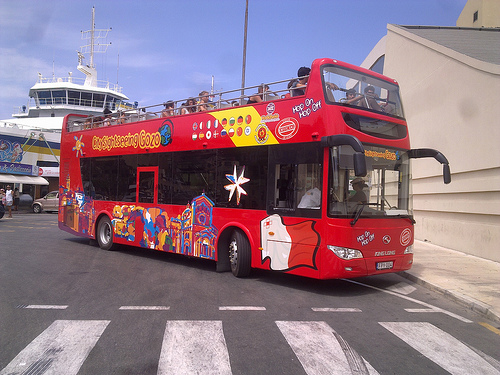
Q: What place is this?
A: It is a road.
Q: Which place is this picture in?
A: It is at the road.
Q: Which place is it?
A: It is a road.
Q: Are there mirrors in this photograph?
A: Yes, there is a mirror.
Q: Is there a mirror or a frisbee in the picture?
A: Yes, there is a mirror.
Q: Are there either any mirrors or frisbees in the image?
A: Yes, there is a mirror.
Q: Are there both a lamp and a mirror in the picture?
A: No, there is a mirror but no lamps.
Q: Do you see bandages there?
A: No, there are no bandages.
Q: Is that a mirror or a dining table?
A: That is a mirror.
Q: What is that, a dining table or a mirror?
A: That is a mirror.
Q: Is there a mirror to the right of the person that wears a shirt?
A: Yes, there is a mirror to the right of the person.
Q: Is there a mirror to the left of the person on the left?
A: No, the mirror is to the right of the person.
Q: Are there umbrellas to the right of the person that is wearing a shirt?
A: No, there is a mirror to the right of the person.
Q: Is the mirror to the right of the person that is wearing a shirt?
A: Yes, the mirror is to the right of the person.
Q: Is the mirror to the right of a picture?
A: No, the mirror is to the right of the person.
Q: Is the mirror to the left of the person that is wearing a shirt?
A: No, the mirror is to the right of the person.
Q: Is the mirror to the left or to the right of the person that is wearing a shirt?
A: The mirror is to the right of the person.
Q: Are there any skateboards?
A: No, there are no skateboards.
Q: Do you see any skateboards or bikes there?
A: No, there are no skateboards or bikes.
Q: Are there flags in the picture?
A: Yes, there is a flag.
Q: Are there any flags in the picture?
A: Yes, there is a flag.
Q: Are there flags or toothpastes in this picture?
A: Yes, there is a flag.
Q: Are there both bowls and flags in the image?
A: No, there is a flag but no bowls.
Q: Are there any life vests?
A: No, there are no life vests.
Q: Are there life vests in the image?
A: No, there are no life vests.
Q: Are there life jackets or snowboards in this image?
A: No, there are no life jackets or snowboards.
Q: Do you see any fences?
A: No, there are no fences.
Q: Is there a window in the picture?
A: Yes, there is a window.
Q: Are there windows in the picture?
A: Yes, there is a window.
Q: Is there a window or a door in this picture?
A: Yes, there is a window.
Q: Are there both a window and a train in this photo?
A: No, there is a window but no trains.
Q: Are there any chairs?
A: No, there are no chairs.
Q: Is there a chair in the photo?
A: No, there are no chairs.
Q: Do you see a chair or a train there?
A: No, there are no chairs or trains.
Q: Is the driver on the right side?
A: Yes, the driver is on the right of the image.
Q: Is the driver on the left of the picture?
A: No, the driver is on the right of the image.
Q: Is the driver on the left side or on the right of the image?
A: The driver is on the right of the image.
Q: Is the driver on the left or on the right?
A: The driver is on the right of the image.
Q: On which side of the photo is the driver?
A: The driver is on the right of the image.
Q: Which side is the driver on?
A: The driver is on the right of the image.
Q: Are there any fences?
A: No, there are no fences.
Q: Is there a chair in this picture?
A: No, there are no chairs.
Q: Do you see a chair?
A: No, there are no chairs.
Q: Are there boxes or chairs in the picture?
A: No, there are no chairs or boxes.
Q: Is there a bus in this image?
A: Yes, there is a bus.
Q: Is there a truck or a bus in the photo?
A: Yes, there is a bus.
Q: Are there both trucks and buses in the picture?
A: No, there is a bus but no trucks.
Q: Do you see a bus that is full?
A: Yes, there is a full bus.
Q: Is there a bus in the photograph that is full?
A: Yes, there is a bus that is full.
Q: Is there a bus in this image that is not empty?
A: Yes, there is an full bus.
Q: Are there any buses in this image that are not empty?
A: Yes, there is an full bus.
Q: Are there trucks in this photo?
A: No, there are no trucks.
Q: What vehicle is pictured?
A: The vehicle is a bus.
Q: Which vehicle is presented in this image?
A: The vehicle is a bus.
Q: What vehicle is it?
A: The vehicle is a bus.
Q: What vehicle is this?
A: This is a bus.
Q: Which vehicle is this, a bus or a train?
A: This is a bus.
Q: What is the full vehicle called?
A: The vehicle is a bus.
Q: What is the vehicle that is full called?
A: The vehicle is a bus.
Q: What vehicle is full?
A: The vehicle is a bus.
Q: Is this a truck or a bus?
A: This is a bus.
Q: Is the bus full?
A: Yes, the bus is full.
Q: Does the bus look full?
A: Yes, the bus is full.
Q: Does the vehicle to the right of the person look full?
A: Yes, the bus is full.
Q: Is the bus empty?
A: No, the bus is full.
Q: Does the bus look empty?
A: No, the bus is full.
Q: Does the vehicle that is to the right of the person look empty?
A: No, the bus is full.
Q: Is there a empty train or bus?
A: No, there is a bus but it is full.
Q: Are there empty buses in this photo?
A: No, there is a bus but it is full.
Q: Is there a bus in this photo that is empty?
A: No, there is a bus but it is full.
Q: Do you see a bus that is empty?
A: No, there is a bus but it is full.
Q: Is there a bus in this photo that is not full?
A: No, there is a bus but it is full.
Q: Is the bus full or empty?
A: The bus is full.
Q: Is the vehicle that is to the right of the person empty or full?
A: The bus is full.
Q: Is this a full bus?
A: Yes, this is a full bus.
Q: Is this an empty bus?
A: No, this is a full bus.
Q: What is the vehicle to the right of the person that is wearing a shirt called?
A: The vehicle is a bus.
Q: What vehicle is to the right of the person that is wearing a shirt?
A: The vehicle is a bus.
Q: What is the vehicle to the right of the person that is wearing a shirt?
A: The vehicle is a bus.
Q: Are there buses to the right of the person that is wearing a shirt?
A: Yes, there is a bus to the right of the person.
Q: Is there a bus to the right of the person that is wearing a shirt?
A: Yes, there is a bus to the right of the person.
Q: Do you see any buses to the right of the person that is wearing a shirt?
A: Yes, there is a bus to the right of the person.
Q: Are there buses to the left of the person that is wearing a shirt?
A: No, the bus is to the right of the person.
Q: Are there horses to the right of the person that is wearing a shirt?
A: No, there is a bus to the right of the person.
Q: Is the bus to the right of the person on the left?
A: Yes, the bus is to the right of the person.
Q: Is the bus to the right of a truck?
A: No, the bus is to the right of the person.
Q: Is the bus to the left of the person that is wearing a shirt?
A: No, the bus is to the right of the person.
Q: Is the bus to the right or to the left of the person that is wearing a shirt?
A: The bus is to the right of the person.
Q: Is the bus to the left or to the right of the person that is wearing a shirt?
A: The bus is to the right of the person.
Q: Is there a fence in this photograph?
A: No, there are no fences.